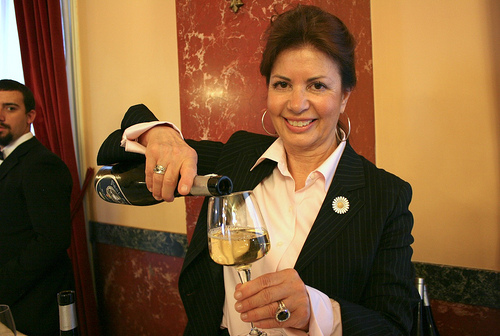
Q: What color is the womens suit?
A: Black.